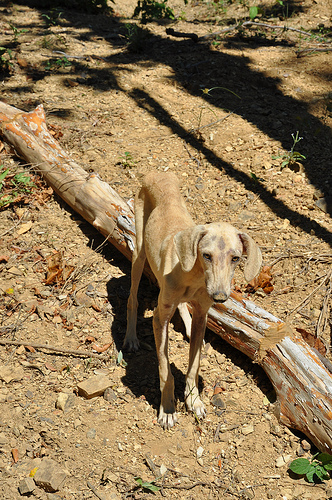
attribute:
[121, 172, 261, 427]
dog — brown, skinny, very thin, large, thin, starving, standing, dirty, yellow, emaciated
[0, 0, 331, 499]
ground — dirty, brown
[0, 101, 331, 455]
log — weathered, orange, sawed, odd shaped, brown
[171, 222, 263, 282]
ears — brown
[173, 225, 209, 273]
ear — brown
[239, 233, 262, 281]
ear — brown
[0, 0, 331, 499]
leaves — dead, green, dried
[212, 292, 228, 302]
nose — dry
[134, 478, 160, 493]
leaf — green, small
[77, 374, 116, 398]
brick — small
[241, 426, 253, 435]
rock — white, small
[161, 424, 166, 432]
nail — black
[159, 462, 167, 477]
leaf — gold, tiny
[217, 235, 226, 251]
gray spot — small